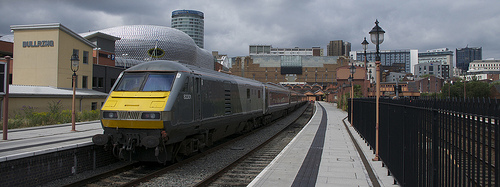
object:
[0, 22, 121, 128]
building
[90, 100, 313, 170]
track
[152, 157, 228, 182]
gravel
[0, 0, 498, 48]
cloud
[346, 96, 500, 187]
gate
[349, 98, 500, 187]
metal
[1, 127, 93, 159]
platform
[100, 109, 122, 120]
headlights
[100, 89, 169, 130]
front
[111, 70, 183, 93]
window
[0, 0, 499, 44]
sky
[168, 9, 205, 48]
skyscraper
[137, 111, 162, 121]
headlights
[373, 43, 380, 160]
pole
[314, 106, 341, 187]
sidewalk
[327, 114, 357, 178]
brick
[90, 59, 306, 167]
train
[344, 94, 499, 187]
fence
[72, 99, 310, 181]
railroad tracks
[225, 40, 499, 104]
background buildings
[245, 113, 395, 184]
ground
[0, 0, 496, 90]
background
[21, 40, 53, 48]
letters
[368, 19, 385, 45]
lamp